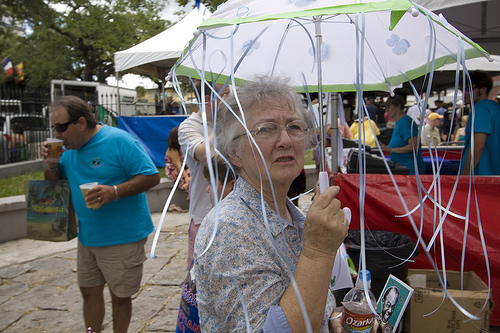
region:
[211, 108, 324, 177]
Glasses on a woman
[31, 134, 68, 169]
Beer being drank by a man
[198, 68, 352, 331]
Old woman standing up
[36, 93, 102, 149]
Glasses on a man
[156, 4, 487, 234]
Umbrella held by a woman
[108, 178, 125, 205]
Bracelett on a man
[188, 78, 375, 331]
woman standing under umbrella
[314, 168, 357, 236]
handle of umbrella is white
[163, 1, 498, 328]
umbrella has hanging ribbon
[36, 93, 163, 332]
man is holding two beer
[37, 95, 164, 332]
man is drinking beer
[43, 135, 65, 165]
full cup of beer in right hand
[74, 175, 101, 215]
cup of beer in left hand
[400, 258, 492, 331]
cardboard box on ground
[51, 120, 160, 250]
man wearing blue shirt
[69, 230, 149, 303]
man wearing khaki shorts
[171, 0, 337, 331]
old woman holding an umbrella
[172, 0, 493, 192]
blue white and green umbrella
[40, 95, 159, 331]
man in blue sipping beer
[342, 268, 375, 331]
ozarks water bottle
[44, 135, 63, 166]
clear cup with beer in it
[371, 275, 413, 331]
blue sign with mans head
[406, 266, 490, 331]
brown cardboard box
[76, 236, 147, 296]
man has on khaki shorts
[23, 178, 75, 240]
tropical looking sign in background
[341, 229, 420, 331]
trash can with trashbag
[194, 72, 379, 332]
the older woman standing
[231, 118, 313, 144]
the clear eye glasses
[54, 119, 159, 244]
the short sleeved blue shirt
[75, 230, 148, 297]
the light brown shorts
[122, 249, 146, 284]
the flap for the pocket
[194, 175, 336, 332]
the blue shirt with small flowers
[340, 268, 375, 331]
the clear water bottle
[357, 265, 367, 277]
the blue plastic cap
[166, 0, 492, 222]
the white opened umbrella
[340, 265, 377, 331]
the clear plastic bottle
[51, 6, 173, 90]
this is a tree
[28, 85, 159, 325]
this is a person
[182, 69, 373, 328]
this is a person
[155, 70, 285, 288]
this is a person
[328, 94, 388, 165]
this is a person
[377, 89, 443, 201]
this is a person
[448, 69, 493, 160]
this is a person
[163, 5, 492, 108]
this is an umbrella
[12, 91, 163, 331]
man drinking from paper cup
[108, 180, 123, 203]
silver bracelet on man's wrist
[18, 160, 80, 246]
brown paper bag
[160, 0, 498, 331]
woman holding umbrella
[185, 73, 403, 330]
older white adult female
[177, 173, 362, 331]
adult female flowered shirt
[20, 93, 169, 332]
adult male drinking beverage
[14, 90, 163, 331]
man wearing blue tee shirt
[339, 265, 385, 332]
plastic water bottle with blue cap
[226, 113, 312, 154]
silver framed glasses on woman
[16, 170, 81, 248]
shopping bag on man's arm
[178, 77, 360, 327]
woman holding a white umbrella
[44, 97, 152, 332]
man wearing blue shirt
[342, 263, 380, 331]
water bottle woman is holding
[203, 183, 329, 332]
patterned shirt woman is wearing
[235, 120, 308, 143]
eye glasses woman is wearing